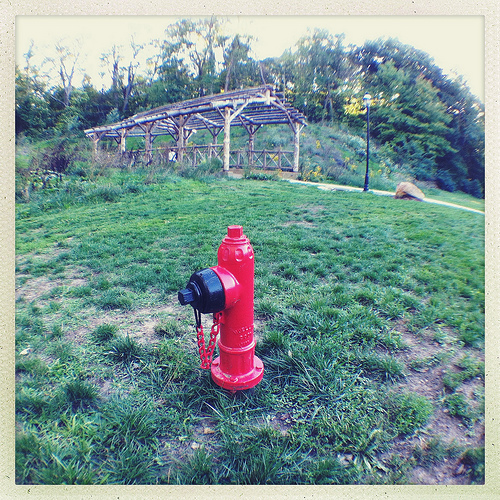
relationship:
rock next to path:
[394, 180, 427, 201] [276, 176, 484, 219]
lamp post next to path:
[362, 92, 373, 192] [276, 176, 484, 219]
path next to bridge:
[276, 176, 484, 219] [83, 82, 308, 182]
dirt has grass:
[161, 412, 221, 473] [182, 421, 189, 439]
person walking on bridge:
[167, 147, 177, 170] [83, 82, 308, 182]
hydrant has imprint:
[180, 223, 266, 391] [236, 325, 256, 344]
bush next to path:
[298, 163, 326, 182] [276, 176, 484, 219]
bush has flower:
[298, 163, 326, 182] [312, 171, 315, 175]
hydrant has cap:
[180, 223, 266, 391] [178, 267, 225, 314]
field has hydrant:
[16, 176, 484, 485] [180, 223, 266, 391]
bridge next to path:
[83, 82, 308, 182] [276, 176, 484, 219]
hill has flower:
[98, 125, 393, 182] [314, 140, 322, 148]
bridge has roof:
[83, 82, 308, 182] [85, 84, 312, 133]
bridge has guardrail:
[83, 82, 308, 182] [94, 143, 227, 172]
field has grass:
[16, 176, 484, 485] [99, 472, 112, 486]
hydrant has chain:
[180, 223, 266, 391] [194, 311, 221, 371]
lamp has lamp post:
[362, 94, 373, 108] [362, 104, 372, 193]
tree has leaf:
[15, 37, 40, 132] [24, 66, 30, 72]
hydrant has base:
[180, 223, 266, 391] [211, 354, 264, 392]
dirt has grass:
[161, 412, 221, 473] [99, 472, 112, 486]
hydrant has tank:
[180, 223, 266, 391] [218, 240, 255, 375]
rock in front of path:
[394, 180, 427, 201] [276, 176, 484, 219]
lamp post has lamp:
[362, 104, 372, 193] [362, 94, 373, 108]